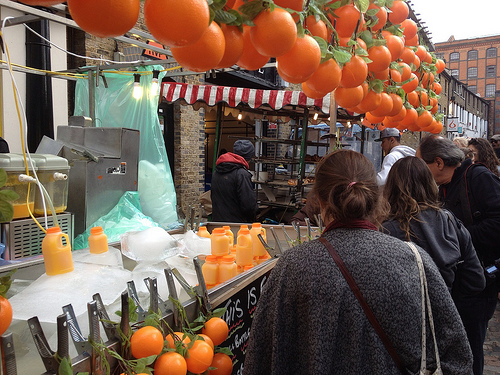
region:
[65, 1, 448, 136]
Oranges at a fruit stand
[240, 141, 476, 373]
Woman wearing grey sweater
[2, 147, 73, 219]
Orange juice in large plastic containers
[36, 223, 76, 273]
Jug of orange juice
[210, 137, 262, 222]
Person in a black coat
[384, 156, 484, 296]
Woman with dark brown hair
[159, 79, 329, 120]
Red and white awning on building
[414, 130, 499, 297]
Man with balding hair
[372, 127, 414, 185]
Man with a grey hat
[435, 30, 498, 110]
Large red brick building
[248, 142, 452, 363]
a woman that is walking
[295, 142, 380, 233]
the head of a grown woman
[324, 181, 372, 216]
the hair of a grown woman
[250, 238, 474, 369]
the back of a grown woman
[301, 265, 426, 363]
the jacket of a grown woman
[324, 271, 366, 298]
the purse strap of a grown woman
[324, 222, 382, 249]
the collar of a grown woman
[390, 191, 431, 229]
the brown hair of a grown woman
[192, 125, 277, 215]
a guy in a jacket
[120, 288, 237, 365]
a bunch of oranges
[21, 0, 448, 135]
decorative ranges hanging from a canopy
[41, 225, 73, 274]
a jug of orange juice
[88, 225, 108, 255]
a small jug of orange juice on a block of ice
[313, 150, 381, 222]
woman with brown hair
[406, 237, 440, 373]
white straps of a purse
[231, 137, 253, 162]
man wearing a gray hat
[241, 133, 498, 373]
people walking by an orange juice stall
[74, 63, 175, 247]
a green plastic bag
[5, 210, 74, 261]
a gray air conditioner unit in a window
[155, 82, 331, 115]
a white and red stripe canopy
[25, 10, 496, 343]
Some people are at a shopping center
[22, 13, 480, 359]
The people are doing some shopping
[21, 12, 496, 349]
The people are looking for bargains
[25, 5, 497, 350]
The people are male and female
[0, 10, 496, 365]
The people are spending their money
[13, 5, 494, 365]
The people are out in the daytime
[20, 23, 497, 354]
Some people are on their lunch break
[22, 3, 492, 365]
The people are inside the city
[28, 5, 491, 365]
The people are patronizing a business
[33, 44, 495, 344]
The people are enjoying the day